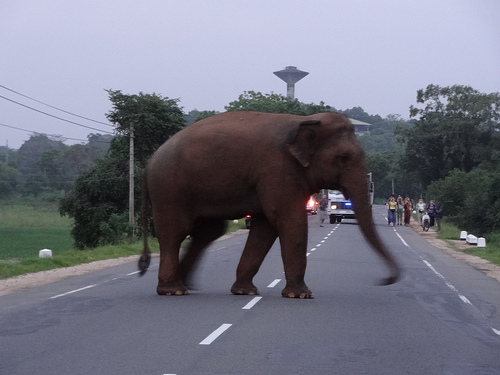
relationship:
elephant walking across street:
[133, 108, 403, 298] [5, 199, 484, 369]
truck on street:
[320, 168, 380, 224] [5, 199, 484, 369]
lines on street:
[192, 220, 354, 344] [5, 199, 484, 369]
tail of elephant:
[135, 177, 153, 275] [133, 108, 403, 298]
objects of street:
[457, 227, 484, 247] [5, 199, 484, 369]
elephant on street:
[133, 108, 403, 298] [5, 199, 484, 369]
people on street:
[382, 191, 440, 231] [5, 199, 484, 369]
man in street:
[313, 189, 330, 225] [5, 199, 484, 369]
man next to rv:
[313, 189, 330, 225] [323, 165, 376, 224]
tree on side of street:
[405, 86, 498, 190] [5, 199, 484, 369]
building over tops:
[274, 64, 309, 101] [222, 89, 337, 114]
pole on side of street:
[124, 95, 140, 234] [5, 199, 484, 369]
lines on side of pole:
[6, 87, 122, 145] [124, 95, 140, 234]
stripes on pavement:
[195, 222, 351, 345] [7, 200, 483, 369]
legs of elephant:
[155, 210, 314, 296] [133, 108, 403, 298]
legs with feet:
[155, 210, 314, 296] [156, 278, 313, 298]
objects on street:
[457, 227, 484, 247] [5, 199, 484, 369]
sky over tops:
[3, 2, 484, 152] [222, 89, 337, 114]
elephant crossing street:
[133, 108, 403, 298] [5, 199, 484, 369]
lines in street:
[185, 270, 290, 360] [52, 193, 473, 349]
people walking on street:
[382, 191, 440, 231] [78, 191, 475, 342]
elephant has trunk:
[133, 108, 403, 298] [342, 194, 405, 291]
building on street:
[274, 64, 309, 101] [119, 213, 438, 350]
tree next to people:
[426, 169, 498, 240] [389, 196, 443, 233]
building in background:
[274, 64, 309, 101] [62, 61, 451, 196]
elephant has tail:
[133, 108, 403, 298] [140, 198, 152, 281]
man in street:
[313, 189, 330, 225] [207, 219, 452, 355]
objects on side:
[457, 227, 484, 247] [417, 224, 486, 292]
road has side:
[310, 228, 467, 373] [417, 224, 486, 292]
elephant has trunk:
[133, 108, 403, 298] [348, 187, 406, 290]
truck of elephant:
[342, 168, 403, 286] [133, 108, 403, 298]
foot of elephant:
[281, 269, 320, 311] [133, 108, 403, 298]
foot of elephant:
[230, 276, 260, 300] [133, 108, 403, 298]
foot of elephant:
[179, 274, 201, 290] [118, 115, 407, 304]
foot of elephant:
[148, 278, 192, 301] [124, 110, 417, 317]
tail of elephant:
[135, 177, 153, 275] [124, 110, 417, 317]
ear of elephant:
[283, 127, 318, 183] [133, 108, 403, 298]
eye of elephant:
[327, 154, 354, 170] [133, 108, 403, 298]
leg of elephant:
[281, 215, 311, 301] [133, 108, 403, 298]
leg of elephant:
[234, 229, 271, 299] [133, 108, 403, 298]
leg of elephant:
[153, 233, 180, 295] [133, 108, 403, 298]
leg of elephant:
[184, 229, 222, 291] [133, 108, 403, 298]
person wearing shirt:
[384, 193, 398, 223] [389, 202, 396, 209]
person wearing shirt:
[399, 198, 413, 229] [403, 201, 410, 211]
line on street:
[197, 320, 227, 343] [5, 199, 484, 369]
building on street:
[274, 64, 309, 101] [5, 199, 484, 369]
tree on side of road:
[55, 84, 180, 262] [0, 206, 500, 371]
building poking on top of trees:
[274, 64, 309, 101] [1, 79, 496, 246]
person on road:
[395, 198, 413, 230] [384, 222, 454, 267]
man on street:
[313, 189, 330, 225] [312, 218, 355, 245]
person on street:
[384, 193, 398, 223] [377, 216, 420, 237]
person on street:
[413, 193, 425, 222] [384, 207, 447, 239]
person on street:
[401, 194, 415, 226] [377, 214, 444, 250]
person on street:
[426, 196, 438, 230] [377, 214, 444, 244]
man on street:
[313, 189, 330, 225] [312, 216, 362, 257]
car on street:
[319, 189, 359, 227] [313, 220, 367, 267]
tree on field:
[55, 84, 180, 262] [2, 200, 143, 278]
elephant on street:
[133, 108, 403, 298] [41, 242, 473, 354]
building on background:
[274, 64, 309, 101] [10, 73, 499, 103]